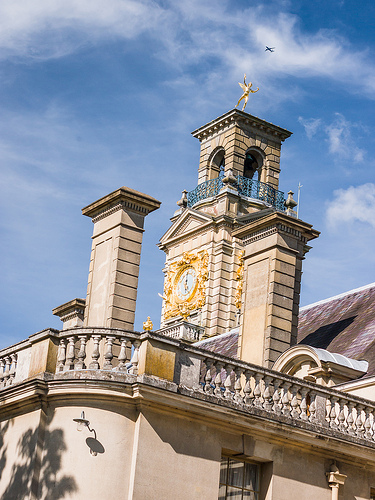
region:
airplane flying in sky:
[265, 44, 274, 53]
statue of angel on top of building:
[233, 73, 260, 113]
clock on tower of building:
[171, 263, 199, 303]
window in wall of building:
[218, 453, 271, 498]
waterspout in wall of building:
[327, 462, 347, 498]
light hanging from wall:
[73, 410, 97, 445]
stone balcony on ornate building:
[4, 327, 374, 454]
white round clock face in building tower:
[170, 264, 202, 304]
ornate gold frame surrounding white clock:
[158, 247, 210, 317]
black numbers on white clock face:
[177, 272, 194, 298]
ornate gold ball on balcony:
[141, 315, 153, 333]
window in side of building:
[218, 453, 272, 498]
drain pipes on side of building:
[327, 463, 350, 496]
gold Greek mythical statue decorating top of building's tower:
[232, 70, 263, 109]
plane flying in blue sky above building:
[261, 44, 275, 54]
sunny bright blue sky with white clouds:
[1, 3, 373, 346]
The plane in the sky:
[253, 36, 282, 64]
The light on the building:
[70, 407, 106, 442]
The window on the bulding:
[213, 441, 269, 499]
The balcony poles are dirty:
[61, 330, 137, 378]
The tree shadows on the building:
[7, 407, 85, 485]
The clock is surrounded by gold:
[155, 242, 217, 305]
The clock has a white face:
[174, 264, 198, 294]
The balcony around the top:
[179, 173, 292, 205]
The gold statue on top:
[223, 67, 262, 107]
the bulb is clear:
[75, 427, 92, 434]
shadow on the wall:
[81, 428, 107, 455]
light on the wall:
[73, 409, 99, 441]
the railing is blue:
[193, 180, 283, 203]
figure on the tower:
[235, 75, 252, 108]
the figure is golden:
[234, 68, 250, 101]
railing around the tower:
[195, 122, 289, 207]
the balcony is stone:
[183, 360, 354, 428]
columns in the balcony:
[204, 372, 258, 396]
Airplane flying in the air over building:
[262, 44, 273, 52]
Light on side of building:
[73, 409, 97, 437]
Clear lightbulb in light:
[76, 420, 82, 431]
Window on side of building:
[217, 445, 274, 498]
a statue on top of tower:
[224, 59, 260, 116]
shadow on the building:
[4, 397, 87, 498]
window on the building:
[204, 438, 282, 499]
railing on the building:
[4, 313, 374, 467]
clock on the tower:
[158, 243, 216, 322]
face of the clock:
[168, 257, 199, 298]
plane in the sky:
[258, 41, 277, 57]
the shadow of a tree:
[11, 421, 84, 498]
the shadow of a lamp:
[69, 436, 111, 463]